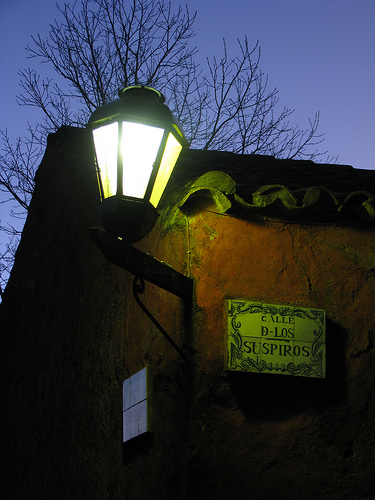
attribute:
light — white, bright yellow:
[86, 84, 191, 241]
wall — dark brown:
[1, 124, 188, 499]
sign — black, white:
[225, 298, 329, 380]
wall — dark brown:
[185, 197, 374, 499]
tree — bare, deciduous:
[1, 0, 338, 302]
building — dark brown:
[1, 126, 374, 500]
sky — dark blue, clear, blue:
[1, 1, 375, 307]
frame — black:
[86, 85, 187, 243]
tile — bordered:
[222, 298, 329, 381]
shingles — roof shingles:
[44, 125, 375, 223]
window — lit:
[118, 365, 152, 447]